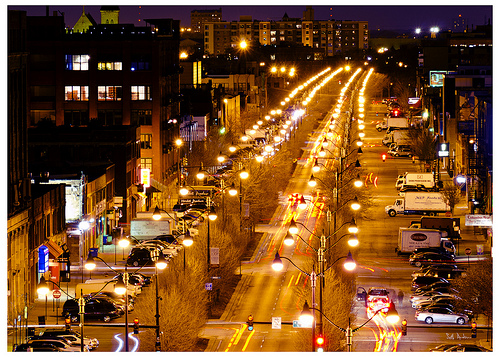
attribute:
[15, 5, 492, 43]
sky — APARTMENT , DO NOT ENTER, purple, small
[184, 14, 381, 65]
building — orange, brown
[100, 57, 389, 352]
lights — orange, green, lit, on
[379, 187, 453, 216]
truck — wide, parked, big, white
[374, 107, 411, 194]
light — red traffic stop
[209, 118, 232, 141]
light — GREEN TRAFFIC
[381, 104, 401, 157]
light — RED TRAFFIC 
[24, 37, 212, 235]
buildings — BACKGROUND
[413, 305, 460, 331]
door — DRIVER'S , OPEN